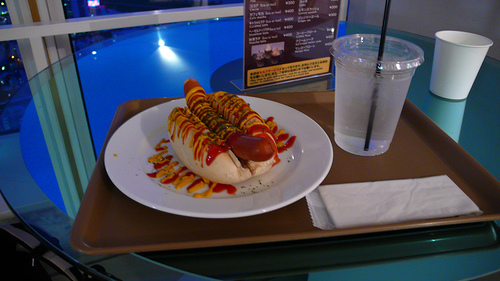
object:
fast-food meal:
[146, 78, 295, 199]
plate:
[104, 94, 332, 219]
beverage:
[330, 32, 425, 156]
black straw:
[363, 0, 393, 151]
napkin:
[304, 174, 483, 231]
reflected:
[149, 28, 192, 76]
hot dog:
[184, 78, 275, 162]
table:
[0, 15, 500, 281]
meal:
[139, 76, 319, 208]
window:
[0, 0, 246, 213]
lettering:
[244, 1, 342, 90]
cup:
[429, 30, 493, 101]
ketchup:
[205, 143, 226, 167]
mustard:
[186, 92, 247, 136]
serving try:
[68, 89, 500, 254]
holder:
[230, 0, 341, 91]